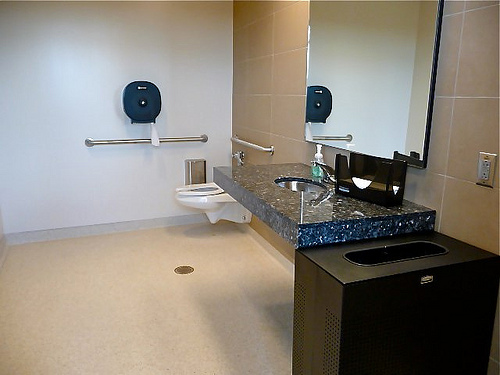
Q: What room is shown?
A: Bathroom.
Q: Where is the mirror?
A: On the wall.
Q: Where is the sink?
A: Below the mirror.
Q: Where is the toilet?
A: Behind the sink.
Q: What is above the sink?
A: The mirror.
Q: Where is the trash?
A: Beside the sink.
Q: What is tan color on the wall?
A: Tiles.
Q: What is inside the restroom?
A: Black trash bin.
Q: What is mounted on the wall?
A: Mirror.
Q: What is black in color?
A: Waste bin.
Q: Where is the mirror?
A: On the wall.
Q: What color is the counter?
A: Marble.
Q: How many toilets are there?
A: One.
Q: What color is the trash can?
A: Black.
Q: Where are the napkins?
A: Counter.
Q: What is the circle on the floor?
A: Drain.